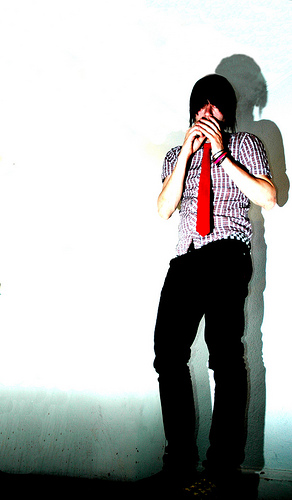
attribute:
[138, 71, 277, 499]
boy — in the picture, standing, alone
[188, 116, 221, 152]
fingers — these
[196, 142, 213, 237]
tie — in the picture, red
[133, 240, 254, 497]
legs — these, apart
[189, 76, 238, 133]
hair — in the picture, black, long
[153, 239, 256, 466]
pants — black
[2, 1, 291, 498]
wall — in the picture, white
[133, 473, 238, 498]
shoes — black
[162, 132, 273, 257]
shirt — striped